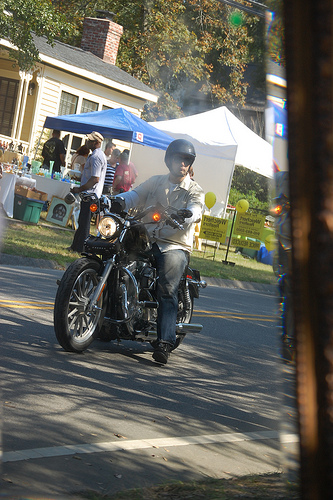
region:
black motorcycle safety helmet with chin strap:
[162, 137, 197, 178]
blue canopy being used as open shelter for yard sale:
[30, 106, 188, 239]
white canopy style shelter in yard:
[123, 104, 272, 250]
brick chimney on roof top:
[76, 7, 125, 67]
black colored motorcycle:
[50, 191, 209, 351]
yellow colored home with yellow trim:
[1, 6, 160, 181]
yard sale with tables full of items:
[0, 110, 270, 266]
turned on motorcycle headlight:
[94, 212, 123, 241]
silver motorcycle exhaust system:
[147, 306, 205, 336]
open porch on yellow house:
[2, 46, 41, 148]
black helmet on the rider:
[162, 136, 195, 185]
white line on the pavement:
[34, 430, 169, 468]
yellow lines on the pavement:
[208, 304, 261, 325]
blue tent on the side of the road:
[43, 104, 167, 150]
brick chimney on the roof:
[77, 9, 124, 67]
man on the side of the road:
[63, 135, 106, 248]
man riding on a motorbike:
[40, 111, 235, 363]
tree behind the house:
[140, 13, 216, 97]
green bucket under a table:
[16, 190, 44, 223]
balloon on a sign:
[233, 192, 259, 219]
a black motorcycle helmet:
[164, 138, 194, 176]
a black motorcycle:
[51, 186, 203, 344]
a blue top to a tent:
[42, 105, 174, 147]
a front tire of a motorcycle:
[54, 255, 105, 350]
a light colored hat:
[85, 129, 100, 139]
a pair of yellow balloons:
[203, 187, 247, 212]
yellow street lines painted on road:
[0, 284, 275, 324]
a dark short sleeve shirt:
[42, 138, 61, 163]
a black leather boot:
[151, 341, 167, 360]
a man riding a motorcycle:
[54, 140, 206, 360]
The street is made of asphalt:
[19, 368, 264, 421]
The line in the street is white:
[68, 426, 276, 460]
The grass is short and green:
[9, 225, 59, 257]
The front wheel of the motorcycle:
[49, 248, 107, 358]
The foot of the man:
[142, 335, 177, 365]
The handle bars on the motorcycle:
[74, 187, 184, 235]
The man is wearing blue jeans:
[155, 248, 184, 347]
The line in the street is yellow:
[192, 306, 280, 326]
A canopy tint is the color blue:
[40, 101, 185, 164]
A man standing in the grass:
[63, 129, 111, 256]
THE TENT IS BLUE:
[35, 105, 186, 157]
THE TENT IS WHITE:
[141, 98, 275, 185]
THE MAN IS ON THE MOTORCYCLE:
[44, 135, 210, 363]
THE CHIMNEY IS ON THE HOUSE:
[79, 0, 128, 70]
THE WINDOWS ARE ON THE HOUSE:
[50, 74, 128, 163]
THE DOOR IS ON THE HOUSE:
[0, 74, 24, 137]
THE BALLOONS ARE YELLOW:
[197, 189, 254, 214]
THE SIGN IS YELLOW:
[195, 205, 233, 251]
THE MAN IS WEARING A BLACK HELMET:
[154, 135, 193, 165]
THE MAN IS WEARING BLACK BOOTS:
[147, 338, 177, 367]